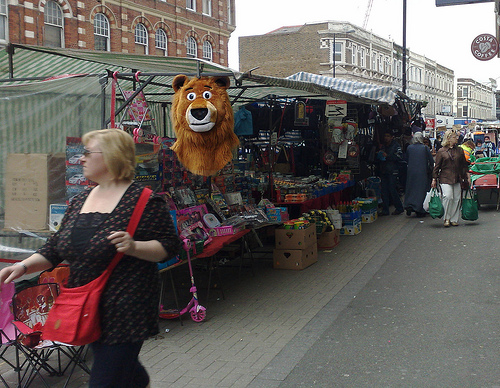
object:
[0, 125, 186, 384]
woman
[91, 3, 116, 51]
window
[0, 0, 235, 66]
building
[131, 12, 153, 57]
window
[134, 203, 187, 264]
arm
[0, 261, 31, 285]
hand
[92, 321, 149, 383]
leg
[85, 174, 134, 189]
neck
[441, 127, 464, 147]
head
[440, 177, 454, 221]
leg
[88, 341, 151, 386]
pants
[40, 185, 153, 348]
purse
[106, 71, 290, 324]
booth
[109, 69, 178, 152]
stroller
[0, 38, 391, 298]
tent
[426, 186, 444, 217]
bag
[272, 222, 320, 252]
boxes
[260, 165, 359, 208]
table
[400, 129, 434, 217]
woman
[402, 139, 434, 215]
coat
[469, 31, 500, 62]
coffee sign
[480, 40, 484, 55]
coffee beans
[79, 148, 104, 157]
glasses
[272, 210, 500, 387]
road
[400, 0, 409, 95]
pole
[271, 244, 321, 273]
boxes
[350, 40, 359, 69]
windows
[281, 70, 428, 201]
tent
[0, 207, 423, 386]
sidewalk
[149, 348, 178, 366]
bricks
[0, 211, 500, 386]
ground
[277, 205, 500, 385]
asphalt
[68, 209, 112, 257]
shirt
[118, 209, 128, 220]
pattern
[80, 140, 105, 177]
face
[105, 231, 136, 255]
hand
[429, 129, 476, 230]
woman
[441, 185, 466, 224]
pants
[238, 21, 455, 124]
building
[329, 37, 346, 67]
window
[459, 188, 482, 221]
bag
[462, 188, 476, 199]
handles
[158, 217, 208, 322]
scooter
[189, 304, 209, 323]
wheel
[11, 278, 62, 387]
folding chair